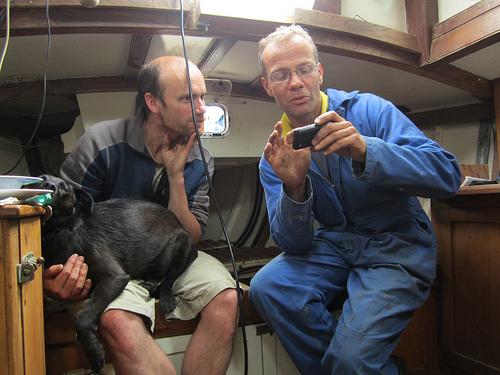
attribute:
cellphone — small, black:
[291, 122, 324, 148]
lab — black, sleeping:
[20, 176, 201, 374]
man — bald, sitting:
[44, 56, 238, 374]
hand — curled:
[36, 252, 98, 305]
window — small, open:
[199, 99, 232, 136]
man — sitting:
[251, 25, 465, 374]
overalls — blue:
[247, 89, 462, 374]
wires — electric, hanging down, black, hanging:
[0, 0, 249, 375]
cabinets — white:
[104, 319, 304, 375]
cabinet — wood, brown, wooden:
[3, 200, 57, 375]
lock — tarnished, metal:
[16, 251, 47, 290]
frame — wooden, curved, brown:
[3, 0, 493, 138]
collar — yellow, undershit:
[280, 88, 330, 148]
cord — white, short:
[1, 1, 12, 80]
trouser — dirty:
[252, 213, 437, 374]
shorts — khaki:
[98, 244, 236, 333]